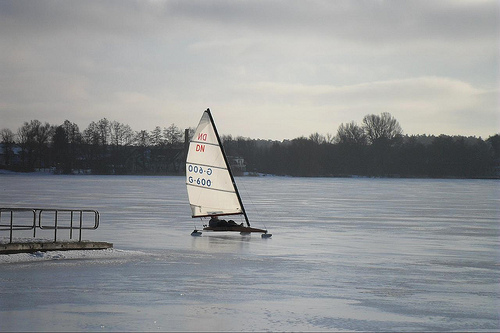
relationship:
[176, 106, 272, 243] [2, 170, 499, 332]
sailboat on water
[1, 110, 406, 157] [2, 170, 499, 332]
trees line water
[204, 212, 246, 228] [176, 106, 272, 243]
man on sailboat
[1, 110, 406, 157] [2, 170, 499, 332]
trees behind water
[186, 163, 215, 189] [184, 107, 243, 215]
letters on sail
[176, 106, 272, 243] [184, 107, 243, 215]
sailboat with sail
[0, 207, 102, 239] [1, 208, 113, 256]
handrail on dock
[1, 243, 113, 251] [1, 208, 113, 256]
sidewalk on dock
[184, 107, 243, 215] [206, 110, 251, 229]
sail has mast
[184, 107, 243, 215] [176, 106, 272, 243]
sail on sailboat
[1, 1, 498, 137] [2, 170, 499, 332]
sky above water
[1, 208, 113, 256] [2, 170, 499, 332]
dock by water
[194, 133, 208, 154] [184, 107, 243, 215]
letters on sail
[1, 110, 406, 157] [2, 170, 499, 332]
trees above water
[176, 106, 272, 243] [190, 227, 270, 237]
sailboat has deck